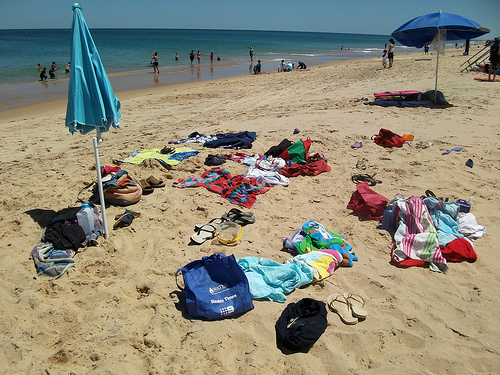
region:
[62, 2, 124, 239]
a blue umbrella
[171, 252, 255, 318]
a blue bag on the sand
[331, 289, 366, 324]
a pair of flip flops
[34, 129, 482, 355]
various belongings left on the beach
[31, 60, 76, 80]
people playing in the ocean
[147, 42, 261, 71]
people walking by the ocean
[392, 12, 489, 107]
a blue umbrella on the beach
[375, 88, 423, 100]
an horizontal beach chair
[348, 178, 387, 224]
a red bag on the sand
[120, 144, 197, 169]
a yellow and blue beach towel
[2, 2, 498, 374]
Ocean beach with sand, personal belongings and visitors.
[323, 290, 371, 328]
Pair of flip-flops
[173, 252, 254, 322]
Blue beach bag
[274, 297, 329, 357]
Black fanny pack.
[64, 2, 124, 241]
Closed light blue beach umbrellla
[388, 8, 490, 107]
Dark blue opened beach umbrella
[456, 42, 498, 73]
Wooden stairs angling down to beach.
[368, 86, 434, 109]
Reclining beach lounge on the beach in the shade.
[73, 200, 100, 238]
Plastic water jug with blue cap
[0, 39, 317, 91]
Wet ocean shore with people in swimsuits in surf.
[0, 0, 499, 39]
The sky is blue.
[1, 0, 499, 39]
The sky is clear.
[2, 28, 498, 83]
The water is blue.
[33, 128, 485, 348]
Clothes are on the ground.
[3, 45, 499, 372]
The ground is sand.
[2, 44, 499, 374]
The sand is tan.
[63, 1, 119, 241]
An umbrella.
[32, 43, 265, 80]
People are in the water.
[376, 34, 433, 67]
People are on the beach.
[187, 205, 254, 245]
Pairs of shoes.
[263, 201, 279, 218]
part of a beach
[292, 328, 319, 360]
part of a short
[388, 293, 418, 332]
part of a snad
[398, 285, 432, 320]
part of a beach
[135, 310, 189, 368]
part of a beach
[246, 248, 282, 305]
part of a cloth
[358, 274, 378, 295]
part of a beach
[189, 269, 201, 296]
side of a bag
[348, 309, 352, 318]
edge of a slipper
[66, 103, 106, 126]
part of an umbrella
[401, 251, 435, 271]
part of a towel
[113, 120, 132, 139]
part of the sea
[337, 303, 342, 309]
side of a slipper